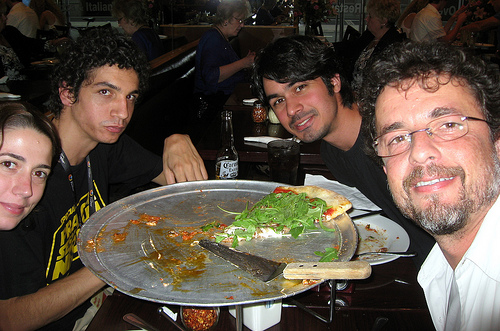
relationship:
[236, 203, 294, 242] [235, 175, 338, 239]
basil on top of pizza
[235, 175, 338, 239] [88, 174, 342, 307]
pizza on top of pan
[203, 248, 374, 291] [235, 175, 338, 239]
spatula for serving pizza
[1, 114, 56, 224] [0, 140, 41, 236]
woman has face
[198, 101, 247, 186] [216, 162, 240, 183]
bottle has beer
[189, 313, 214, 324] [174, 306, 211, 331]
pepper in jar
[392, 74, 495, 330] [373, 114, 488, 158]
man has glasses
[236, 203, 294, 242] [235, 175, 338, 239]
basil on pizza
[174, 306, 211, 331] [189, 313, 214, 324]
jar contains pepper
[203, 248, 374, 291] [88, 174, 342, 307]
spatula sits on pan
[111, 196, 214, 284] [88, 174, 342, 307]
pizza sauce on pan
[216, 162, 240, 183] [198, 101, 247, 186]
beer in bottle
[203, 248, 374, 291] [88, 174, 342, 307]
spatula on top of pan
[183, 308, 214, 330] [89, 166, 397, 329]
pepper sitting on table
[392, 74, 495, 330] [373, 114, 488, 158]
man wears glasses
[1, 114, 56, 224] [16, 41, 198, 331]
woman next to man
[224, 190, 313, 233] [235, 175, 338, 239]
lettuce sits on pizza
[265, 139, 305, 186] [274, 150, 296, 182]
cup filled with water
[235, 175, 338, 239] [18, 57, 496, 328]
pizza among people